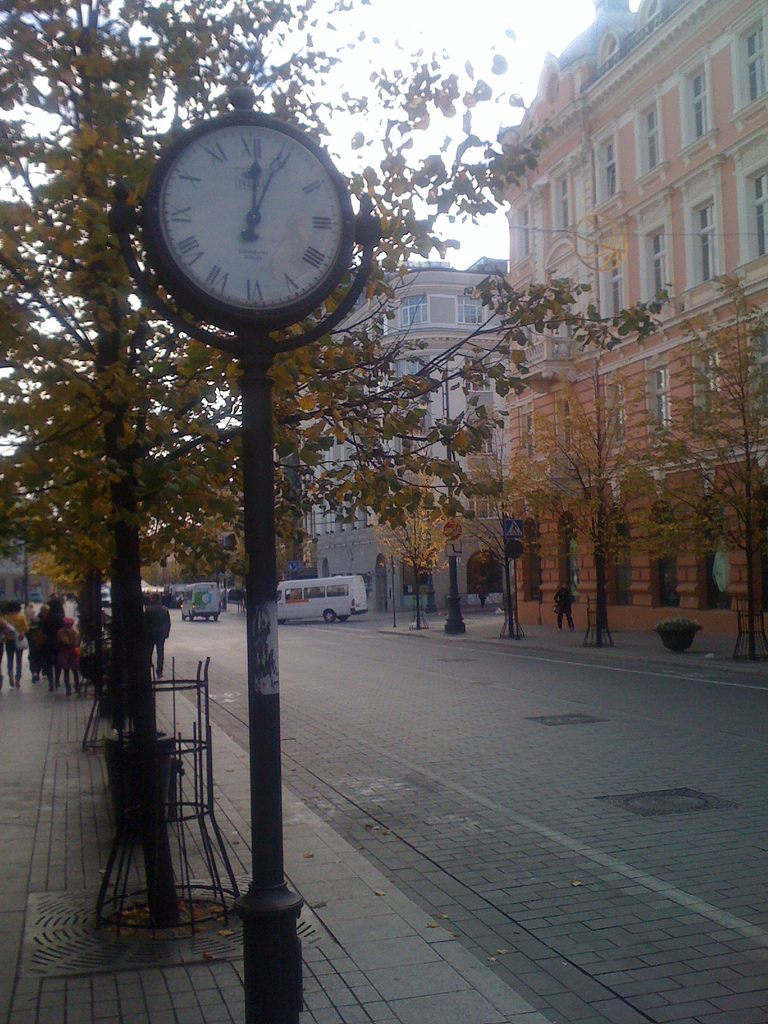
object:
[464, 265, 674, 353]
leaves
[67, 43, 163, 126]
leaves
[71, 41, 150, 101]
leaves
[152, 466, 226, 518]
leaves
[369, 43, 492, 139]
leaves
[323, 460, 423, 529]
leaves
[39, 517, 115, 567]
leaves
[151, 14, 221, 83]
leaves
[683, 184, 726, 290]
window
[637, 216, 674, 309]
window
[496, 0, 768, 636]
building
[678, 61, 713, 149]
window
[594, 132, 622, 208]
window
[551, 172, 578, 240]
window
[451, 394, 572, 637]
tree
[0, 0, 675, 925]
tree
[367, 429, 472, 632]
tree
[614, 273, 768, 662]
tree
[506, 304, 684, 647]
tree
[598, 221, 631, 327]
window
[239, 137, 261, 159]
numeral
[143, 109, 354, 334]
clock